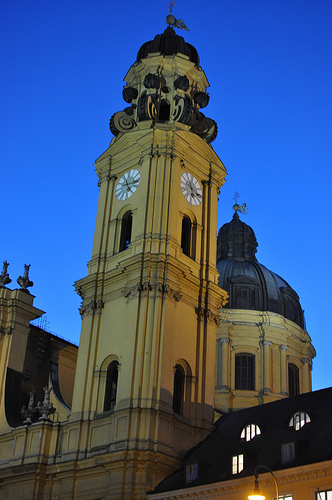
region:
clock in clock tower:
[112, 163, 144, 208]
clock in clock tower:
[179, 168, 209, 209]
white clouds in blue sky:
[4, 105, 44, 149]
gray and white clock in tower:
[113, 167, 146, 201]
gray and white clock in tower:
[179, 163, 209, 210]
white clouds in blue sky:
[11, 170, 63, 220]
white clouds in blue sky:
[228, 65, 276, 124]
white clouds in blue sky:
[258, 36, 299, 65]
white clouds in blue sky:
[51, 25, 84, 66]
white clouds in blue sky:
[37, 86, 73, 130]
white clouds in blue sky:
[239, 49, 280, 113]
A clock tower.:
[69, 0, 221, 488]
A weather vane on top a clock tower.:
[161, 0, 191, 31]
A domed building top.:
[214, 210, 307, 325]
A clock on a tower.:
[177, 167, 204, 209]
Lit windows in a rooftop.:
[223, 415, 262, 474]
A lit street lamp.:
[247, 464, 283, 499]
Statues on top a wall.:
[0, 256, 36, 291]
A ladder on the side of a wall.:
[36, 314, 50, 376]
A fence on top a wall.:
[32, 325, 78, 341]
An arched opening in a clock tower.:
[110, 201, 136, 255]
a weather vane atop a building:
[165, 2, 189, 35]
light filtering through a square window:
[232, 453, 247, 474]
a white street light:
[243, 493, 265, 498]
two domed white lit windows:
[240, 413, 308, 439]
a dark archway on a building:
[100, 357, 121, 415]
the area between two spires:
[15, 325, 87, 426]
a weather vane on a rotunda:
[229, 188, 248, 218]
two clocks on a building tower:
[117, 166, 205, 204]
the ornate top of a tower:
[108, 54, 217, 141]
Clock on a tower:
[180, 168, 205, 204]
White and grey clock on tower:
[179, 170, 205, 207]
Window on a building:
[232, 348, 256, 394]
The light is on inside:
[229, 452, 246, 475]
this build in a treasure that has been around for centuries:
[75, 5, 248, 311]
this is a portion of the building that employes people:
[158, 390, 329, 497]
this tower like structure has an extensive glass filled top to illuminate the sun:
[212, 191, 313, 408]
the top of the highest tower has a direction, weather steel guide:
[117, 5, 229, 128]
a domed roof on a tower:
[135, 23, 199, 63]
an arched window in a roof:
[237, 422, 264, 440]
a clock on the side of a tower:
[180, 172, 204, 205]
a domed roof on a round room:
[208, 251, 307, 328]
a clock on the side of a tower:
[115, 170, 141, 198]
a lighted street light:
[248, 464, 282, 499]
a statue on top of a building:
[34, 386, 54, 422]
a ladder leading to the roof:
[33, 316, 51, 378]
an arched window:
[97, 356, 121, 413]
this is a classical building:
[10, 17, 279, 387]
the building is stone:
[51, 333, 186, 460]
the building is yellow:
[85, 322, 169, 478]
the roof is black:
[205, 413, 265, 468]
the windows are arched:
[78, 355, 132, 429]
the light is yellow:
[232, 487, 271, 498]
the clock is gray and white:
[96, 176, 168, 196]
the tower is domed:
[213, 194, 288, 287]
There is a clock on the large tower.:
[178, 165, 199, 211]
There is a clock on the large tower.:
[113, 167, 139, 199]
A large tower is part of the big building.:
[71, 3, 227, 441]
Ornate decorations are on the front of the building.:
[15, 383, 58, 420]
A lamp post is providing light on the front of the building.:
[243, 462, 279, 498]